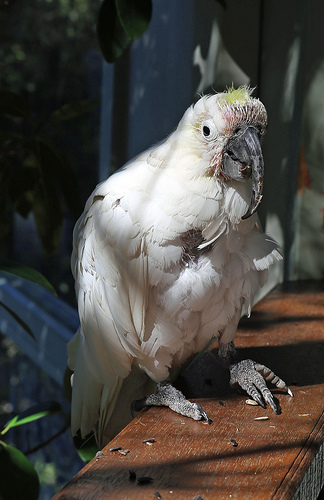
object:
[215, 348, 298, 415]
foot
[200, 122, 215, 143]
eye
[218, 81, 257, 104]
tuft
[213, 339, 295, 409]
leg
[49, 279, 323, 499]
platform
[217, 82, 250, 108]
feathers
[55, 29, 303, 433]
feathers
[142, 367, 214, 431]
feet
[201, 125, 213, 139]
eye ball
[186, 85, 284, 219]
face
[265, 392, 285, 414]
nail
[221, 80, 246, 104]
hair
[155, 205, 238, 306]
breast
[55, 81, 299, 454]
parrot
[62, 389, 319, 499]
panel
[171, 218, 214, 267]
pluck feathers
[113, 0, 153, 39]
leaf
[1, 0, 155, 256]
leaves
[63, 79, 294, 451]
bird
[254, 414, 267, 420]
seed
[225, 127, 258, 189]
beak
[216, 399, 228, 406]
seed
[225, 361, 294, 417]
claw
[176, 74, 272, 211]
bird's head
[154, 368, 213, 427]
right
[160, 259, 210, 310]
bald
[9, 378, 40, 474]
down